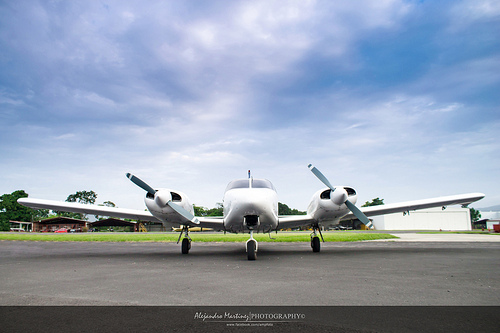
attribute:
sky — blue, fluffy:
[17, 10, 489, 194]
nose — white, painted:
[221, 187, 280, 232]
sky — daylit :
[25, 5, 481, 160]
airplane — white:
[13, 162, 483, 266]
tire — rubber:
[309, 235, 323, 255]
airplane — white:
[139, 147, 374, 262]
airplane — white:
[14, 156, 491, 261]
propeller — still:
[122, 167, 207, 231]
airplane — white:
[11, 160, 498, 297]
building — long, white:
[352, 199, 475, 237]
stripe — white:
[307, 162, 315, 169]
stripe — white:
[125, 171, 134, 181]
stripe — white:
[364, 220, 373, 229]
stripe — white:
[190, 215, 201, 223]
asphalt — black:
[265, 269, 389, 296]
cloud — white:
[146, 16, 322, 160]